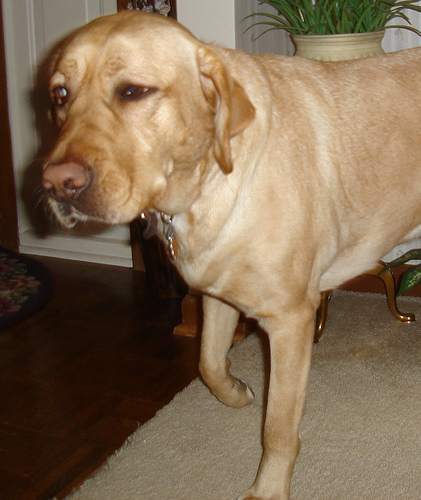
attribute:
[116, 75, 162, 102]
eye — closed, squinting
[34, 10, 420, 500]
dog — old, standing, looking, tan, brown, walking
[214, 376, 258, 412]
paw — lifted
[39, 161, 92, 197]
nose — brown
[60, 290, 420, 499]
carpet — gray, white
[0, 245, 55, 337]
rug — black, floral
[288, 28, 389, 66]
pot — white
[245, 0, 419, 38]
plant — green, grass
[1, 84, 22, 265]
door — wooden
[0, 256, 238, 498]
floor — wooden